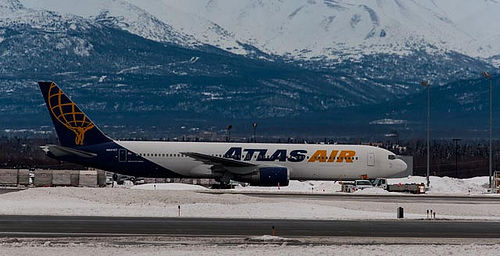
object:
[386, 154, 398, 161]
window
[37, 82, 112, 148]
tail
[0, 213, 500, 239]
runway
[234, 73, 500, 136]
mountain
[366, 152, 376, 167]
door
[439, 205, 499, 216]
snow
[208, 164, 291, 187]
engine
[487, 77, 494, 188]
pole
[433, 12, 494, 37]
snow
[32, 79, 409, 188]
air liner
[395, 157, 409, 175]
nose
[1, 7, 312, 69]
mountain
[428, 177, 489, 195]
snow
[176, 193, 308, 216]
snow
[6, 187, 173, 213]
snow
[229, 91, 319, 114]
mountains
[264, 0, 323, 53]
snow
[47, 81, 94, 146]
logo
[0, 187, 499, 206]
runway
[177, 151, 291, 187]
wing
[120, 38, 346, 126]
mountain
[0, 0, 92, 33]
snow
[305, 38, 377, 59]
snow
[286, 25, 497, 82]
mountain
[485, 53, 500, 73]
mountain